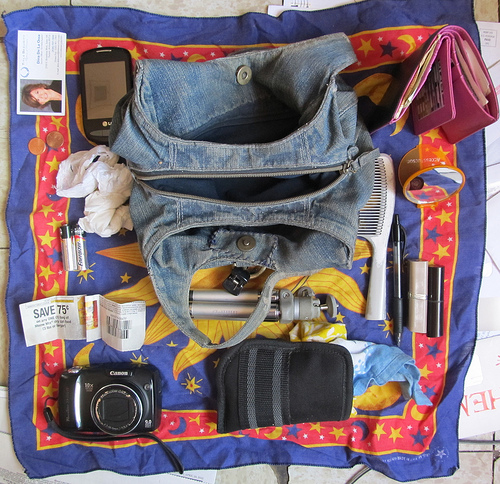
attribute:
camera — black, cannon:
[59, 363, 159, 437]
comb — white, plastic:
[359, 153, 394, 322]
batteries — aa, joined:
[61, 225, 91, 273]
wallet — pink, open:
[370, 27, 500, 146]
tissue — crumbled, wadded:
[56, 143, 137, 238]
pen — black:
[391, 212, 405, 350]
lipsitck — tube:
[429, 266, 442, 339]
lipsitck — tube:
[410, 260, 428, 332]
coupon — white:
[17, 292, 146, 353]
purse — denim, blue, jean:
[107, 32, 381, 350]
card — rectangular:
[17, 29, 68, 119]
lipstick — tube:
[408, 258, 429, 334]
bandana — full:
[186, 422, 460, 481]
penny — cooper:
[28, 138, 46, 156]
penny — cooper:
[45, 130, 64, 149]